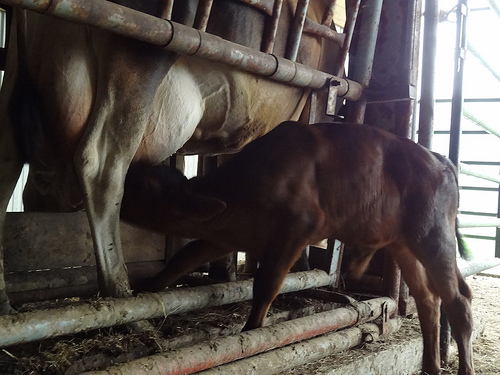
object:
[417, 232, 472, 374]
leg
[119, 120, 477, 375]
cow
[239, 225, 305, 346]
front leg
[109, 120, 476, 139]
baby cow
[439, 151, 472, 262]
tail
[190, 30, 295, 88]
brown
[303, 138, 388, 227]
brown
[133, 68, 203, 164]
udder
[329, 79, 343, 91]
nut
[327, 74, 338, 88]
bolt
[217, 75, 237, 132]
veins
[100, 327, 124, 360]
hay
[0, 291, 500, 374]
ground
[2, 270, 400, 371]
pipes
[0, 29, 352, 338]
cow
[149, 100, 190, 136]
white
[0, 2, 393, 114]
enclosure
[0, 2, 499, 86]
barn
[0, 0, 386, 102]
cage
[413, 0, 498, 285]
metal fence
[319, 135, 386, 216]
muscles